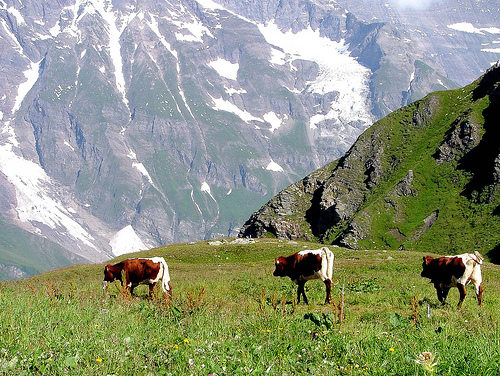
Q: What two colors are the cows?
A: White and Brown.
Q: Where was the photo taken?
A: Mountains.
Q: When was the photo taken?
A: Daytime.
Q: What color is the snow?
A: White.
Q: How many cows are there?
A: Three.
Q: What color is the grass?
A: Green.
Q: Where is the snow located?
A: On the mountain.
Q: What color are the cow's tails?
A: White.